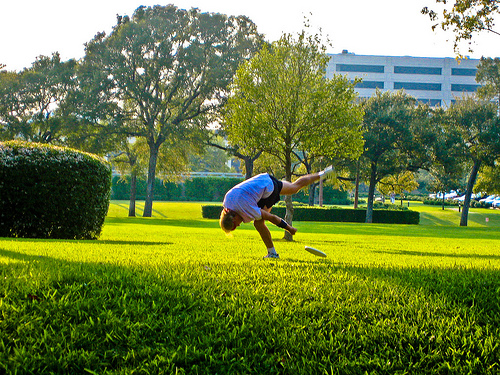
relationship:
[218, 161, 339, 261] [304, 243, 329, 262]
man playing with frisbee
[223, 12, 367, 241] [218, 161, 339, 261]
tree behind man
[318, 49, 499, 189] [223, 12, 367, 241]
building behind tree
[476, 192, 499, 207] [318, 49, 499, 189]
car in front of building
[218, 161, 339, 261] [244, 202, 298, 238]
man has arm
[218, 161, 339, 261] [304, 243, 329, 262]
man trying to catch frisbee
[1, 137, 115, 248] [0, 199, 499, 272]
shrub in grass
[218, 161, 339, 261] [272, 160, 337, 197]
man has leg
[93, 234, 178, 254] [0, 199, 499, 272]
shadow in grass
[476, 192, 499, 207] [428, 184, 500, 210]
car in a parking lot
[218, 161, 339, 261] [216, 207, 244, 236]
man has head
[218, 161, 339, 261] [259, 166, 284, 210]
man dressed in shorts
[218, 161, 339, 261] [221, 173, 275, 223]
man dressed in shirt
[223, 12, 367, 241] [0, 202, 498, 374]
tree growing in field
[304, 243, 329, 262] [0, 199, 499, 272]
frisbee over grass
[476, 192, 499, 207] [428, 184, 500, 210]
car parked on parking lot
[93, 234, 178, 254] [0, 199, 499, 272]
shadow cast on grass